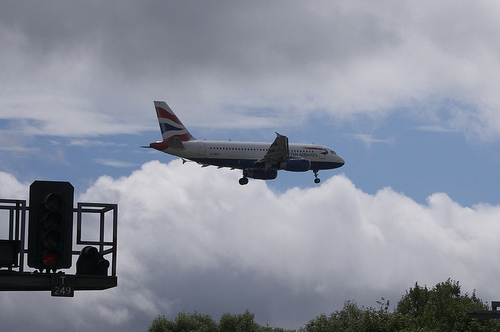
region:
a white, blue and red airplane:
[136, 100, 346, 188]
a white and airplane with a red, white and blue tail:
[139, 100, 346, 186]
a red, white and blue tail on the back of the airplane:
[152, 98, 192, 138]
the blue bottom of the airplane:
[185, 156, 345, 170]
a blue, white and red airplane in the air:
[140, 99, 345, 186]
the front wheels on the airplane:
[312, 170, 322, 182]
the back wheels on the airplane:
[238, 176, 248, 185]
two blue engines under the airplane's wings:
[244, 156, 311, 178]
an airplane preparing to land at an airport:
[123, 87, 373, 199]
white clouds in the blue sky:
[349, 20, 499, 262]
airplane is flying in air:
[138, 97, 345, 184]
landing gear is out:
[234, 160, 322, 185]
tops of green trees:
[151, 281, 498, 330]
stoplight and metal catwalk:
[0, 177, 119, 302]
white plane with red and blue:
[143, 98, 345, 183]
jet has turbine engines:
[239, 155, 310, 181]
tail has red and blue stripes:
[141, 99, 196, 161]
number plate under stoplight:
[51, 273, 71, 297]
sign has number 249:
[51, 274, 73, 296]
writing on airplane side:
[283, 150, 319, 157]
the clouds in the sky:
[364, 70, 494, 235]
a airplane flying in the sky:
[142, 93, 349, 193]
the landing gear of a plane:
[311, 169, 322, 188]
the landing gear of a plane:
[236, 173, 251, 189]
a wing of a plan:
[259, 128, 294, 172]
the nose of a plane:
[326, 147, 348, 167]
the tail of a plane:
[152, 95, 195, 147]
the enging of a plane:
[237, 163, 284, 180]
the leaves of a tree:
[416, 293, 453, 325]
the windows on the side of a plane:
[203, 142, 266, 154]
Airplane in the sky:
[143, 86, 373, 198]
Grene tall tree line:
[138, 302, 208, 327]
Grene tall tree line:
[202, 283, 301, 330]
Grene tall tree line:
[308, 273, 458, 329]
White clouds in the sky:
[361, 170, 438, 217]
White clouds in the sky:
[310, 168, 365, 220]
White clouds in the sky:
[365, 75, 443, 131]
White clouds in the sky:
[269, 91, 414, 135]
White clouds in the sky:
[51, 102, 161, 177]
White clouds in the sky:
[113, 156, 190, 215]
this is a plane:
[116, 79, 351, 203]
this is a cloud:
[121, 183, 185, 253]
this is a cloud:
[290, 206, 395, 276]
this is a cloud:
[399, 208, 463, 274]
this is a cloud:
[144, 235, 238, 286]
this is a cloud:
[219, 7, 326, 81]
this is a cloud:
[344, 9, 427, 88]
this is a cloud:
[27, 53, 116, 133]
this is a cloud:
[174, 227, 263, 302]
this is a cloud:
[286, 249, 338, 296]